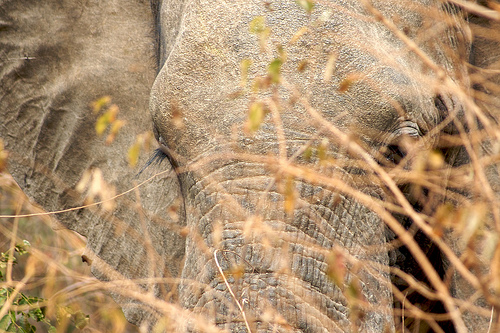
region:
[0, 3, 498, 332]
close view of elephant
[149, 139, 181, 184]
right eye of elephant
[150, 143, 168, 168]
long black eyelashes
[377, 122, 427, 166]
left eye of elephant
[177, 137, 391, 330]
base of the trunk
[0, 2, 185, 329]
right ear of the elephant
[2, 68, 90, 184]
veins displayed on the right ear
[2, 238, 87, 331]
green vegetation in front of elephant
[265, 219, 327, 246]
couple of wrinkles on the elephants trunk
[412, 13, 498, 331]
some of the dried weeds in front of the elephant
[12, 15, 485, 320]
curved tan branches in front of elephant head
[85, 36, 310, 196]
small and dried leaves along branches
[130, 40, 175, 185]
curved skin above black eyelashes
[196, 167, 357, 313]
skin surface broken up into rectangles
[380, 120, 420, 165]
dark eye with wrinkled lid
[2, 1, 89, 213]
sharp folds along ear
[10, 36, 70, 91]
dark oval depression on ear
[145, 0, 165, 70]
dark line separating ear from head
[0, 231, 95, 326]
green plant with droopy leaves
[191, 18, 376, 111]
gray and tan skin with pebbly texture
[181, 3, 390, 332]
wrinkled gray elephant snout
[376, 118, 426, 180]
left dark eye of elephant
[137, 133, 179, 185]
dark spiky elephant eyelashes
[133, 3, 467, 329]
elephant head behind brown grass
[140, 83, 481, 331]
dry brown grass in front of animal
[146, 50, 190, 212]
eye socket of gray elephant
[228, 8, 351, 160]
brown grass with bits of green leaves on top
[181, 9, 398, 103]
light gray elephant forehead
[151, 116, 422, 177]
two dark elephant eyes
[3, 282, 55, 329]
brown grass with green leaves in background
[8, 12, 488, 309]
gray elephant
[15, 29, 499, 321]
weeds growing in front of elephant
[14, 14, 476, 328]
scaling skin of gray elephant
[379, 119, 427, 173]
left eye of gray elephant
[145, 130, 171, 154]
right eye of gray elephant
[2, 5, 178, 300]
right ear of elephant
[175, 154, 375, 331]
trunk of gray elephant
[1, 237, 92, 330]
grass beside elephant's ear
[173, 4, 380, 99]
forehead of gray elephant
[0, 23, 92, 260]
veins in elephant's ear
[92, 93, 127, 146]
leaves that are blurry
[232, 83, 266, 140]
leaves that are blurry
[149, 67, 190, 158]
eyeball on an elephant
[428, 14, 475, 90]
blurry dead grass on right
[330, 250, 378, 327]
blurry leaves in photo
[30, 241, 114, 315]
blurry leaves on left corner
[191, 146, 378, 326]
elephant trunk on ground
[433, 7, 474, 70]
dead grass in right side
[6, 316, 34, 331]
green leaves in corner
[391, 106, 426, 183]
eyeball of elephant on left side